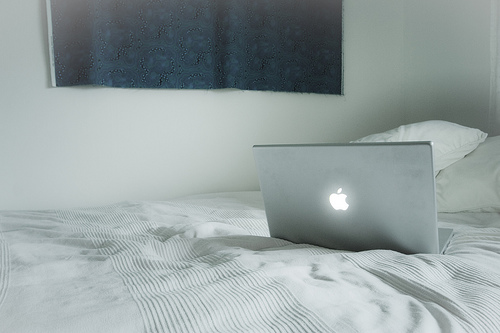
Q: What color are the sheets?
A: White.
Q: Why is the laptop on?
A: It was being used.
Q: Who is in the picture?
A: No one.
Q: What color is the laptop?
A: Silver.